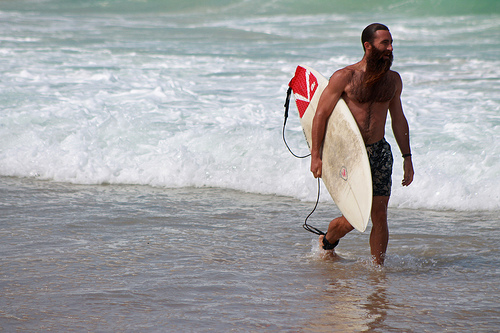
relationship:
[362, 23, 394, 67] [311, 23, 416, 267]
head of man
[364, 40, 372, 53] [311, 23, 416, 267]
ear on man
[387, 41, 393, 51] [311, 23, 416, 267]
nose on man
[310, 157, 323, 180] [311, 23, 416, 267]
hand on man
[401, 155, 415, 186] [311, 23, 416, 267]
hand on man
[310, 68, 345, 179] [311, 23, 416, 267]
arm of man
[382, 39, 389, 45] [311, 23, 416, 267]
eye of man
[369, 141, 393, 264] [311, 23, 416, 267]
leg of man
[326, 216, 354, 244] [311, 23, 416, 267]
leg of man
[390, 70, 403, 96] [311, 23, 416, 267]
shoulder of man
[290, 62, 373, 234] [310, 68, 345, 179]
surfboard under arm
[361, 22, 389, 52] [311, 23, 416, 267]
hair on man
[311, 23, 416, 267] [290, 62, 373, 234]
man carrying surfboard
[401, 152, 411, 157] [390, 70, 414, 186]
band on arm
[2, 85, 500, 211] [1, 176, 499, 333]
wave crashing on beach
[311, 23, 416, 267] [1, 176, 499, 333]
man walking on beach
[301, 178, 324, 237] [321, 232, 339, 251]
leash on band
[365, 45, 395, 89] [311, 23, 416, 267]
beard on man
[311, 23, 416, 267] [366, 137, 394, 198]
man in shorts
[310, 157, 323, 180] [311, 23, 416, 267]
hand of man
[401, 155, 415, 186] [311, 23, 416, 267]
hand of man